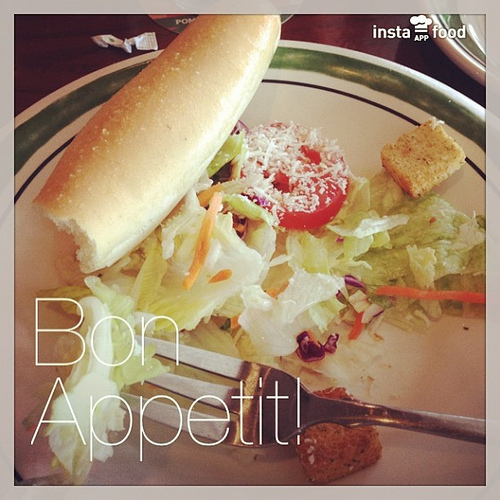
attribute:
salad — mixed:
[38, 82, 431, 347]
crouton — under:
[293, 417, 390, 486]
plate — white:
[456, 321, 475, 336]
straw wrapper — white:
[90, 30, 159, 53]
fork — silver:
[119, 334, 484, 449]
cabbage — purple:
[294, 329, 339, 364]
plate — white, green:
[17, 30, 480, 475]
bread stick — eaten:
[18, 20, 304, 272]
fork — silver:
[113, 323, 486, 465]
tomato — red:
[242, 125, 352, 229]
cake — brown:
[309, 436, 379, 457]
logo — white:
[356, 9, 473, 64]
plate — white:
[52, 47, 499, 427]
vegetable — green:
[223, 189, 498, 369]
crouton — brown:
[376, 106, 465, 202]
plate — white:
[402, 347, 472, 397]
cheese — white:
[241, 125, 346, 228]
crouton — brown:
[377, 115, 469, 205]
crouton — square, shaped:
[376, 121, 466, 198]